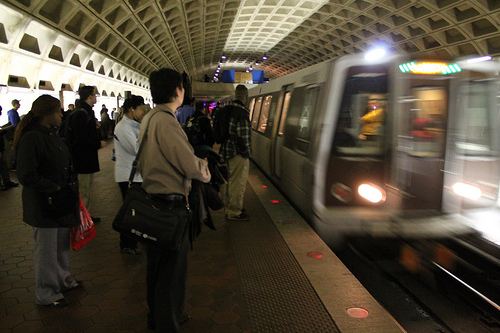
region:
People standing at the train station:
[21, 66, 253, 320]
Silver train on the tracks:
[254, 46, 498, 268]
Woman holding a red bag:
[17, 91, 95, 308]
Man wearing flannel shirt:
[220, 79, 253, 224]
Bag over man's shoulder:
[112, 107, 187, 252]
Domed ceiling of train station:
[17, 26, 496, 86]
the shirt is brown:
[123, 103, 209, 211]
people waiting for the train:
[15, 31, 266, 254]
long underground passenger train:
[212, 45, 499, 244]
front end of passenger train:
[304, 35, 498, 244]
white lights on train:
[354, 173, 484, 211]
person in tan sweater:
[110, 66, 217, 331]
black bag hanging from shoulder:
[104, 109, 198, 254]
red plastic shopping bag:
[65, 188, 100, 258]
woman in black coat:
[4, 93, 94, 315]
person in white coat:
[109, 92, 149, 212]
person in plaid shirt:
[209, 79, 257, 227]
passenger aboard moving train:
[355, 92, 388, 151]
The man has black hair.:
[147, 64, 188, 113]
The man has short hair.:
[147, 64, 186, 112]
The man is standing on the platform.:
[114, 66, 219, 332]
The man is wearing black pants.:
[136, 193, 203, 331]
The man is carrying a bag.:
[109, 64, 212, 320]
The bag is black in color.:
[113, 187, 194, 248]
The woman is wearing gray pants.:
[27, 223, 88, 311]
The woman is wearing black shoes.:
[30, 274, 86, 310]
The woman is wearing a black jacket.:
[11, 94, 95, 309]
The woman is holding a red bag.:
[65, 189, 98, 254]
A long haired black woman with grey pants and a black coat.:
[11, 92, 84, 311]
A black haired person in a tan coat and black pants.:
[136, 68, 212, 331]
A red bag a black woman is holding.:
[72, 190, 94, 252]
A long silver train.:
[216, 52, 498, 251]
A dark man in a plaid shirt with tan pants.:
[217, 84, 253, 221]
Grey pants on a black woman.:
[26, 222, 77, 304]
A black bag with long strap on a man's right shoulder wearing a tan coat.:
[114, 109, 196, 256]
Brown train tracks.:
[365, 234, 498, 326]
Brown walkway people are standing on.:
[0, 137, 375, 332]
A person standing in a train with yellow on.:
[362, 95, 386, 138]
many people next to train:
[11, 58, 286, 218]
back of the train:
[311, 40, 498, 236]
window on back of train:
[383, 76, 463, 166]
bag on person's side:
[88, 97, 212, 267]